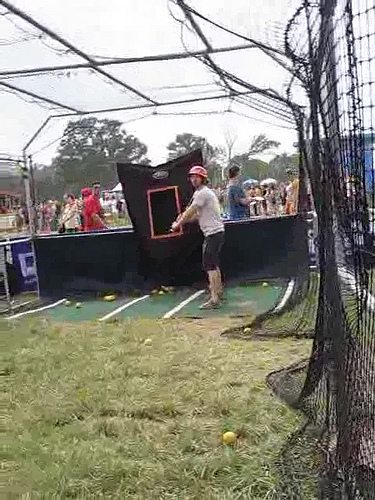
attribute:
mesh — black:
[185, 1, 374, 496]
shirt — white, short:
[181, 186, 244, 238]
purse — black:
[49, 215, 70, 233]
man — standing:
[175, 160, 228, 311]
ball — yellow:
[206, 420, 271, 469]